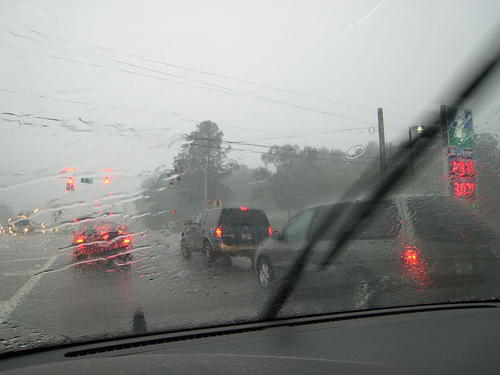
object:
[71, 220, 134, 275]
car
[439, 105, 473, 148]
sign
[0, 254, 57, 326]
lines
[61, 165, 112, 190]
traffic light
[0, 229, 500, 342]
pavement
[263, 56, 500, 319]
wiper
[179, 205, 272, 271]
car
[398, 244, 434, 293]
brake light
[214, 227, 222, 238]
brake light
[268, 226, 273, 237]
brake light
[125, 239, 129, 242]
brake light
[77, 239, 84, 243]
brake light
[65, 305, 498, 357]
vent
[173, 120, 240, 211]
tree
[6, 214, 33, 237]
car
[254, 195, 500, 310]
car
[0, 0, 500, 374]
car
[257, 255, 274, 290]
tire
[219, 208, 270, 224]
window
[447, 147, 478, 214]
sign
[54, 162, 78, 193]
overhead light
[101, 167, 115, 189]
overhead light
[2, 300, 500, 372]
dashboard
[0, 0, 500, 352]
bad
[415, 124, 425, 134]
street light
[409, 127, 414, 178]
pole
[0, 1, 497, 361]
windshield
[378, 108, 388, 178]
pole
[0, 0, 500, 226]
sky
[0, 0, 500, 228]
clouds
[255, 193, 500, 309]
banana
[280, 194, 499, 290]
box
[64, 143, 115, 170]
air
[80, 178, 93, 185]
sign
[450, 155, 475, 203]
numbers